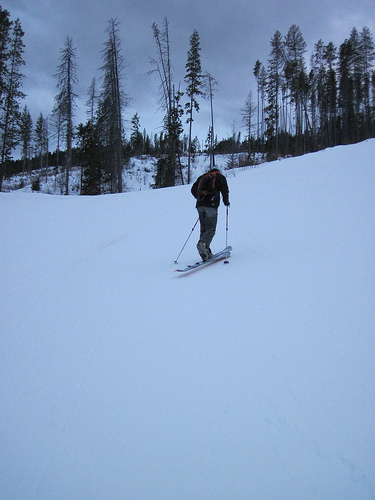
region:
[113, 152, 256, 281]
SKIER ON SKI SLOPE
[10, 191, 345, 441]
SNOW COVERING SKI SLOPE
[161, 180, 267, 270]
SKI POLES IN MAN'S HANDS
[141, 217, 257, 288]
MAN'S FEED ON SKIS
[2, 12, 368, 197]
TALL TREES IN BACKGROUND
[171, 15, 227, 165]
TOP OF A PINE TREE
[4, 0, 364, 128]
SKY IS DULL AND CLOUDY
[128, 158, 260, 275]
SKIER IS GOING UP HILL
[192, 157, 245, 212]
SKIER IS LOOKING DOWN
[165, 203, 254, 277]
SKIER IS WEARING BLUE PANTS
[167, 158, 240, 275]
skier in white snow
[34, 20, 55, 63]
white clouds in blue sky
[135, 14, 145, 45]
white clouds in blue sky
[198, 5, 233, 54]
white clouds in blue sky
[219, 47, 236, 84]
white clouds in blue sky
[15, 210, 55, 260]
white snow on hill side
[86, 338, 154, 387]
white snow on hill side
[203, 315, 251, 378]
white snow on hill side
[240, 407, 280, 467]
white snow on hill side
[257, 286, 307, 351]
white snow on hill side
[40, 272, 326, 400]
the land is sloppy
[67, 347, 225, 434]
snow is on the ground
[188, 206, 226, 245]
the pants are grey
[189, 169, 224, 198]
the bag pack is orange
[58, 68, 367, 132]
the trees are thin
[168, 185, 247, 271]
the guy is holding two skipoles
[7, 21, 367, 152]
the trees are sparsely populated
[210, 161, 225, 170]
the helmet is white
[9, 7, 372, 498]
the scene is outdoors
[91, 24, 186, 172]
the trees are tall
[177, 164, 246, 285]
a man skiing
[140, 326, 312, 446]
the snow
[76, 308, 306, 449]
the snow is white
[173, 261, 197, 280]
skiis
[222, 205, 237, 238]
a ski pole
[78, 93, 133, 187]
the tall trees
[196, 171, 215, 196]
person is wearing a backpack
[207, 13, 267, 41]
the clouds in the sky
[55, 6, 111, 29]
the clouds are dark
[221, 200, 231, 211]
person is holding ski poles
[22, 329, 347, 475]
The snow is the color white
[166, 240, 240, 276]
The skis on the man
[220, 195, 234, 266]
The man is holding a ski stick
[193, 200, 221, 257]
The man is wearing pants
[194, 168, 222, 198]
The man is wearing a backpack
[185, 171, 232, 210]
The man has on a black jacket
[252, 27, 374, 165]
The tree is tall with green leaves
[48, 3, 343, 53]
The sky is the color gray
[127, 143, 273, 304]
The man is skiing on ice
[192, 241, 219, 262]
The shoes of the man